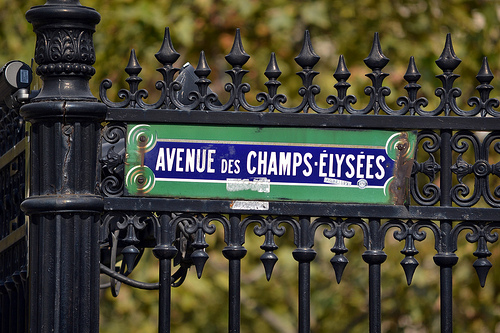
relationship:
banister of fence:
[218, 217, 255, 329] [2, 3, 499, 330]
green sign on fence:
[124, 124, 419, 206] [110, 52, 492, 332]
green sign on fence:
[124, 124, 419, 206] [36, 219, 347, 319]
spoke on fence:
[435, 31, 457, 331] [2, 3, 499, 330]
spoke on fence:
[363, 28, 397, 330] [2, 3, 499, 330]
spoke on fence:
[294, 27, 316, 332] [2, 3, 499, 330]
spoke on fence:
[224, 27, 251, 332] [2, 3, 499, 330]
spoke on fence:
[153, 26, 180, 331] [2, 3, 499, 330]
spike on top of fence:
[436, 37, 469, 80] [32, 37, 485, 272]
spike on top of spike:
[397, 50, 429, 92] [257, 50, 294, 88]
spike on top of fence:
[361, 27, 392, 81] [32, 37, 485, 272]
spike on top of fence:
[330, 47, 357, 83] [32, 37, 485, 272]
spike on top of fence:
[257, 50, 294, 88] [32, 37, 485, 272]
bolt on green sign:
[132, 130, 154, 147] [124, 124, 419, 206]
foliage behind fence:
[192, 18, 355, 62] [70, 227, 445, 312]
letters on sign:
[154, 146, 385, 179] [147, 137, 397, 189]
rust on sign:
[393, 135, 415, 212] [117, 122, 419, 206]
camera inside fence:
[77, 110, 145, 190] [113, 29, 240, 329]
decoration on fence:
[6, 41, 478, 124] [2, 3, 499, 330]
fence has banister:
[22, 3, 500, 332] [144, 207, 182, 331]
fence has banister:
[2, 3, 499, 330] [291, 215, 312, 332]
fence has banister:
[22, 3, 500, 332] [353, 213, 408, 329]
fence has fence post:
[22, 3, 500, 332] [18, 0, 108, 333]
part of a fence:
[120, 66, 150, 111] [142, 13, 262, 328]